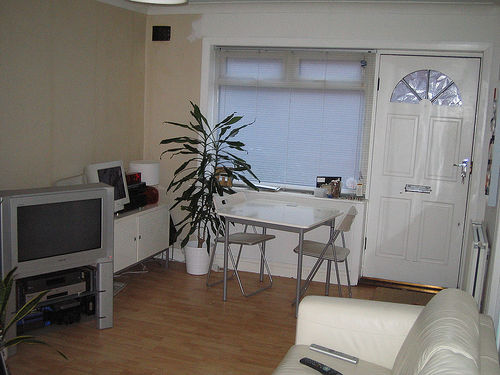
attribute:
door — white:
[360, 53, 483, 296]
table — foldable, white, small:
[215, 196, 345, 320]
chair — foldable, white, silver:
[295, 204, 356, 298]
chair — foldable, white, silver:
[205, 192, 275, 299]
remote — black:
[298, 355, 342, 375]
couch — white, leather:
[269, 289, 500, 375]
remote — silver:
[310, 342, 358, 363]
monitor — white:
[54, 158, 131, 215]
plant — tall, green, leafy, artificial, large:
[155, 100, 263, 255]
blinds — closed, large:
[212, 47, 366, 195]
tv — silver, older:
[1, 182, 114, 281]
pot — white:
[181, 238, 213, 274]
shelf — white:
[110, 205, 173, 273]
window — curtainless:
[209, 43, 377, 198]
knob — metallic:
[450, 157, 472, 185]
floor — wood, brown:
[1, 259, 448, 372]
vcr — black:
[25, 268, 84, 291]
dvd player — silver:
[23, 283, 86, 306]